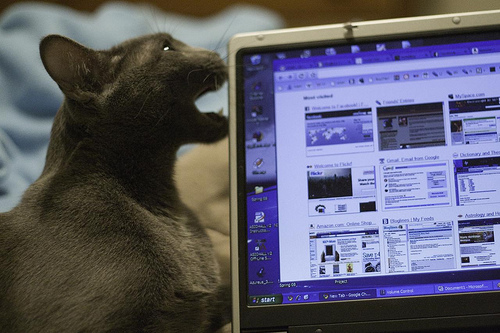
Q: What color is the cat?
A: Black.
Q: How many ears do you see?
A: One.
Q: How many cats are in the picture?
A: One.